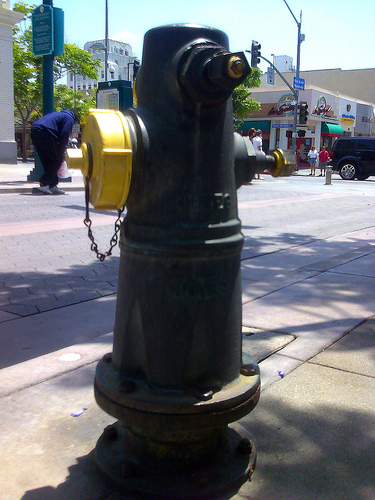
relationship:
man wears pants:
[31, 109, 78, 194] [23, 101, 82, 201]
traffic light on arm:
[249, 40, 261, 68] [244, 48, 298, 99]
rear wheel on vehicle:
[339, 160, 354, 179] [321, 128, 374, 179]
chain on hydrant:
[77, 168, 122, 256] [53, 15, 305, 418]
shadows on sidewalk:
[6, 228, 349, 351] [9, 247, 373, 497]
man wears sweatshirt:
[23, 103, 82, 197] [31, 107, 80, 147]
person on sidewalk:
[318, 146, 329, 175] [293, 164, 336, 176]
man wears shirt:
[31, 109, 78, 194] [30, 110, 75, 141]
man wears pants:
[31, 109, 78, 194] [31, 125, 64, 186]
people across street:
[305, 145, 330, 172] [0, 189, 117, 331]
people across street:
[305, 145, 330, 172] [248, 181, 369, 258]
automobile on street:
[316, 120, 372, 180] [297, 162, 374, 213]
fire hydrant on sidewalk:
[58, 10, 292, 499] [9, 247, 373, 497]